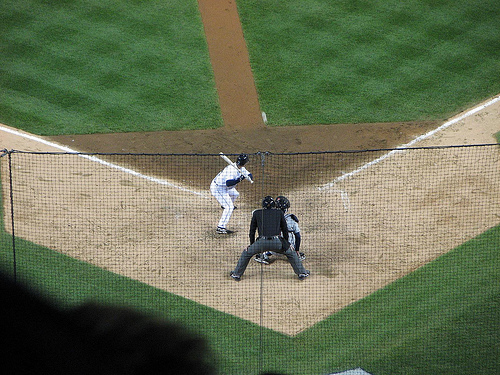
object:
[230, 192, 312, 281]
baseball player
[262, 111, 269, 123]
baseball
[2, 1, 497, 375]
grass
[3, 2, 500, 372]
baseball field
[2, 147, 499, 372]
net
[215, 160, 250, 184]
shirt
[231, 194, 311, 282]
umpire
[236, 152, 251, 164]
helmet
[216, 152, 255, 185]
bat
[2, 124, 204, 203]
line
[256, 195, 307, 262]
catcher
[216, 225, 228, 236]
shoe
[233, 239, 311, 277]
pants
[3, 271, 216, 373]
hair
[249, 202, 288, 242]
shirt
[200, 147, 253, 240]
player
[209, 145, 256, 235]
baseball player